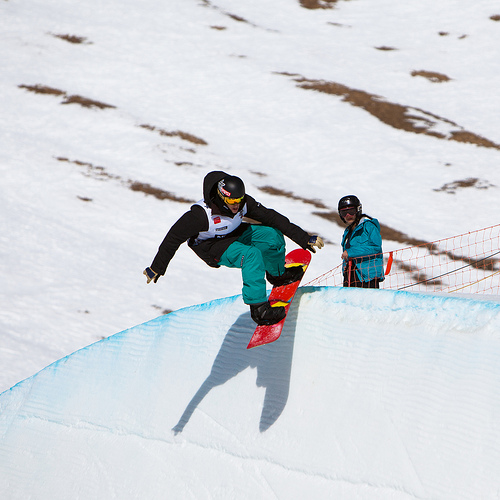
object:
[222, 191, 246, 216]
face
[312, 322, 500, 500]
sun shine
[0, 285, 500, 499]
ice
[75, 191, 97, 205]
mark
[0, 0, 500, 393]
snow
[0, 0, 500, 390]
ground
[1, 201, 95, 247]
track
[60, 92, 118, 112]
dirt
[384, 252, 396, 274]
flag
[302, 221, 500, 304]
fence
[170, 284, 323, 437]
shadow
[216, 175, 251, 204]
helmet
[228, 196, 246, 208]
goggles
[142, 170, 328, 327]
man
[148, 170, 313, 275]
jacket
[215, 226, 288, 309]
ski pants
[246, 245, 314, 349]
snow board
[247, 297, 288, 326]
ski boots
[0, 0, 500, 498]
scene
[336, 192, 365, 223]
helmet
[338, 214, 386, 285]
coat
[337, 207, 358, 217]
goggles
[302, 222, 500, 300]
net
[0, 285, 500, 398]
line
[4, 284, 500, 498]
snow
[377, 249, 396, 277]
ribbon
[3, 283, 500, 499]
hill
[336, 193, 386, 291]
guy